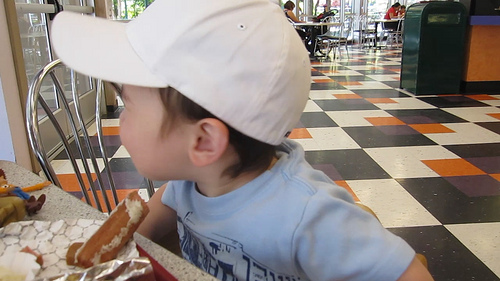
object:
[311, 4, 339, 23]
baby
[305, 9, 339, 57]
stroller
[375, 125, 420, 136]
tile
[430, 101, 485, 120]
floor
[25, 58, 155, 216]
chair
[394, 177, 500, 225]
tile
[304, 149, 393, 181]
tile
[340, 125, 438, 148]
black tile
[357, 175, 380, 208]
floor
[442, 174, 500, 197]
tile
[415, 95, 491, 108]
tiled floor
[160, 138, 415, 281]
shirt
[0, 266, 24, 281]
food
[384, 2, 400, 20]
people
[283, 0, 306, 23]
people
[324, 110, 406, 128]
tile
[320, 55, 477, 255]
floor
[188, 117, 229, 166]
ear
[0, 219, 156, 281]
wrapper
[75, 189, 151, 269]
hotdog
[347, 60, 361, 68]
floor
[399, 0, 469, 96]
trash can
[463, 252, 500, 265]
floor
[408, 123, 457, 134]
tile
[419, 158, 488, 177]
tile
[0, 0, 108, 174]
door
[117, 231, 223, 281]
tray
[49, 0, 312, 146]
baseball cap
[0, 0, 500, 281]
restaurant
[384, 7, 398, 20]
shirt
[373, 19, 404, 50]
table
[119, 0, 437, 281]
boy